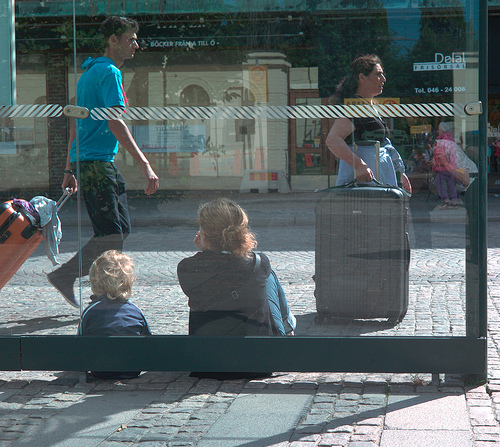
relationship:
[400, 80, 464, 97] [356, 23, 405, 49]
number on window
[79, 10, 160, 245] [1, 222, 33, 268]
man pulling luggage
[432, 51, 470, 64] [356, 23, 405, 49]
name on window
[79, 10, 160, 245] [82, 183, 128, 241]
man wearing pants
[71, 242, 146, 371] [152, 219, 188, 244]
child sitting on pavement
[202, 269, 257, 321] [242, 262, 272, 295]
woman wearing a jacket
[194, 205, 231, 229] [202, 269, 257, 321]
hair of woman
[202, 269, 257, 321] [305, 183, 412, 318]
woman wheeling suitcase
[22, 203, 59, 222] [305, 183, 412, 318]
clothes are piled onto suitcase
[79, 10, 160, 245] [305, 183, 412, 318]
man rolling suitcase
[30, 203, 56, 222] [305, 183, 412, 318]
sweaters on top of suitcase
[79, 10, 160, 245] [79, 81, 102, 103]
man wearing shirt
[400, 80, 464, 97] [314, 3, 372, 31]
number on glass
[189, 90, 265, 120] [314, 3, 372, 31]
stripe on glass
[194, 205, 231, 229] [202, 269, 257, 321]
hair on top of woman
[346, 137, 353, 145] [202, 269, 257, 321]
back of woman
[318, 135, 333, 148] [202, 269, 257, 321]
elbow attached to woman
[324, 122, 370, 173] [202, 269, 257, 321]
arm attached to woman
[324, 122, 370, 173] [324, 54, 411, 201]
arm of woman